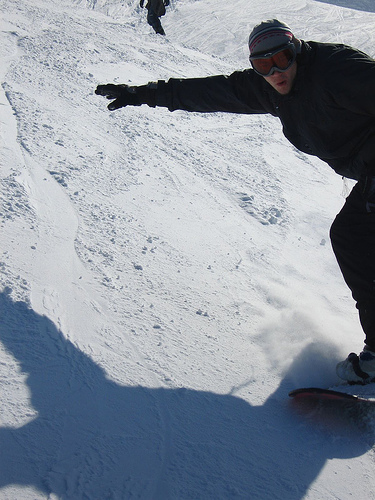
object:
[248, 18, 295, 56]
hat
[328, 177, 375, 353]
pants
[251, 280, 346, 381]
snow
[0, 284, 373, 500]
shadow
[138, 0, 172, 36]
man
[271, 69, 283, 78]
nose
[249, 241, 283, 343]
ground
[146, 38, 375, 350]
clothing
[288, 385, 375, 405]
rim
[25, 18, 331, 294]
ground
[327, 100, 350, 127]
ground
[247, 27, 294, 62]
beanie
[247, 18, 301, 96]
head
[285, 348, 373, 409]
snow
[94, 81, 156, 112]
glove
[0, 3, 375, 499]
snow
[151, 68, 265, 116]
wall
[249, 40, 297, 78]
goggles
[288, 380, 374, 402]
snowboard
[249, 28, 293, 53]
stripe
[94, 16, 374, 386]
man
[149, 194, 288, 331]
tracks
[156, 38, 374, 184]
jacket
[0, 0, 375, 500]
background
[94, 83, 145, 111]
hand